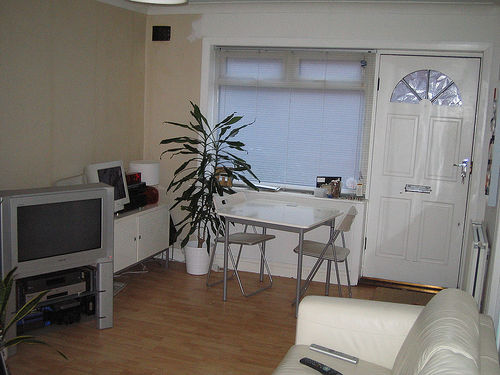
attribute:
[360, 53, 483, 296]
door — white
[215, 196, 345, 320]
table — foldable, white, small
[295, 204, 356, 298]
chair — foldable, white, silver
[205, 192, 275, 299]
chair — foldable, white, silver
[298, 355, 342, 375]
remote — black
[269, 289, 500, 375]
couch — white, leather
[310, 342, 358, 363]
remote — silver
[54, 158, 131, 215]
monitor — white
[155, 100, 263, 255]
plant — tall, green, leafy, artificial, large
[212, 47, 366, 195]
blinds — closed, large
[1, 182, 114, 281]
tv — silver, older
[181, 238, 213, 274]
pot — white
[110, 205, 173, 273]
shelf — white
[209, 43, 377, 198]
window — curtainless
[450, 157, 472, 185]
knob — metallic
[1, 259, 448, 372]
floor — wood, brown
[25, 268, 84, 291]
vcr — black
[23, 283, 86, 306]
dvd player — silver